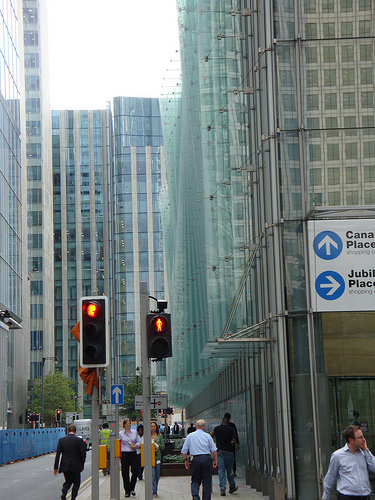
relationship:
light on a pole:
[73, 294, 111, 371] [79, 370, 112, 498]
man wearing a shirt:
[178, 416, 223, 498] [178, 430, 220, 459]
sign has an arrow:
[299, 213, 373, 317] [313, 227, 341, 259]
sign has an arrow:
[299, 213, 373, 317] [313, 269, 347, 301]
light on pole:
[80, 294, 111, 368] [75, 294, 112, 498]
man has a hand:
[320, 418, 375, 497] [361, 437, 368, 451]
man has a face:
[320, 418, 375, 497] [350, 430, 364, 449]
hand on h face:
[361, 437, 368, 451] [350, 430, 364, 449]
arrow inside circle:
[316, 233, 337, 255] [310, 229, 347, 259]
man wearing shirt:
[178, 416, 223, 498] [181, 428, 219, 455]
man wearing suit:
[50, 420, 92, 497] [56, 432, 85, 490]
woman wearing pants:
[113, 413, 144, 498] [119, 448, 141, 491]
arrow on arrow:
[111, 385, 121, 402] [111, 385, 121, 402]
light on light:
[153, 317, 165, 332] [153, 317, 165, 332]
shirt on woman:
[148, 432, 165, 460] [142, 419, 167, 495]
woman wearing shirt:
[142, 419, 167, 495] [148, 432, 165, 460]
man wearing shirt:
[320, 418, 372, 497] [324, 445, 374, 493]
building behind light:
[55, 102, 121, 418] [80, 294, 111, 368]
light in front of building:
[80, 294, 111, 368] [55, 102, 121, 418]